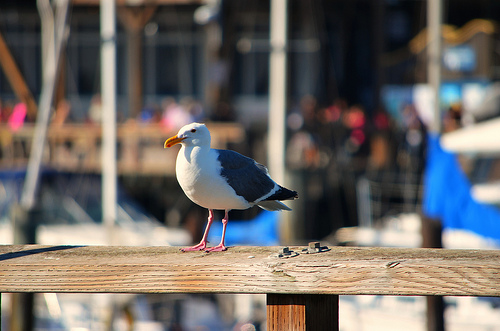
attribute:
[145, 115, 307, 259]
bird — seagull, standing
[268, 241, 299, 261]
bolt — secure, metal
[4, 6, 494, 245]
back — blurry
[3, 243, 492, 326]
rail — wood, brown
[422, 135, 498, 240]
material — blue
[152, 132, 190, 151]
beak — orange, bright orange, slightly curved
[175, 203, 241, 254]
legs — pink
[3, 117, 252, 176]
support beam — wood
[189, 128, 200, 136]
eye — small, black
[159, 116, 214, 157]
head — white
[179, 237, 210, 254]
foot — pink, webbed, orange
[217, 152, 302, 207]
wing — gray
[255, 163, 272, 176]
feather — grey, black, gray